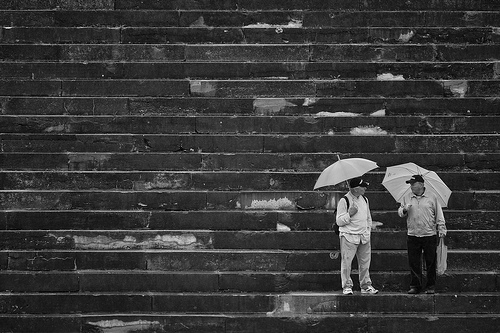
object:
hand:
[438, 225, 448, 237]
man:
[397, 175, 448, 295]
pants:
[407, 236, 439, 289]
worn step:
[69, 232, 213, 251]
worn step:
[253, 98, 297, 116]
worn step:
[376, 71, 404, 80]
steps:
[0, 0, 499, 332]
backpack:
[331, 196, 350, 235]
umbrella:
[312, 154, 379, 191]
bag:
[436, 237, 448, 276]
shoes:
[341, 287, 379, 296]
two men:
[334, 175, 449, 295]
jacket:
[398, 186, 448, 237]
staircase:
[0, 4, 497, 327]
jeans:
[339, 236, 372, 289]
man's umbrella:
[380, 162, 452, 208]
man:
[335, 179, 379, 295]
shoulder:
[336, 191, 354, 219]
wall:
[3, 2, 499, 331]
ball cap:
[405, 175, 425, 185]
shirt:
[336, 190, 373, 245]